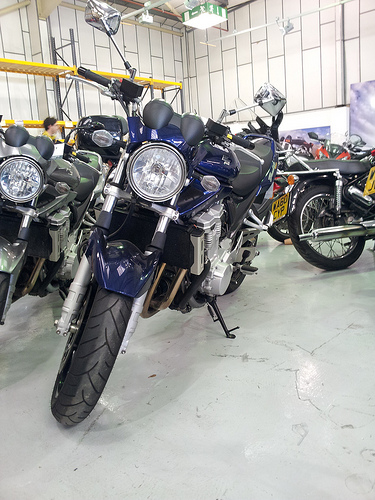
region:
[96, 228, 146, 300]
dark blue colored motorcycle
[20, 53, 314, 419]
A blue and black motorcycle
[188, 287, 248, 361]
Black kickstand to motorcycle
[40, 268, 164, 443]
Front tire of motorcycle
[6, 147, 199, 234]
Two motorcycle head lights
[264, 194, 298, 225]
Yellow and black license plate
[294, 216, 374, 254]
Chrome muffler of motorcycle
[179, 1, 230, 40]
A light with green shade around it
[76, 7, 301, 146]
Two mirrors on bike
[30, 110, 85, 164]
One man in the shop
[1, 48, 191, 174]
A large yellow rack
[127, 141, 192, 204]
headlight on blue motorcycle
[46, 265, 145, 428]
front tire of blue motorcycle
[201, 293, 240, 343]
kick stand holding motorcycle up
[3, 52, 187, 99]
top of yellow shelving unit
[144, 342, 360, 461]
painted concrete flooring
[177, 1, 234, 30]
light on ceiling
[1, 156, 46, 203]
headlight on green motorcycle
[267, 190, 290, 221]
yellow motorcycle license plate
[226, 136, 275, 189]
seat on blue motorcycle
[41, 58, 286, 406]
shiny blue motorcycle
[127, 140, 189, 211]
white round head light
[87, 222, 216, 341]
the tire is black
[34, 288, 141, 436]
the tire is black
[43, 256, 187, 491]
the tire is black